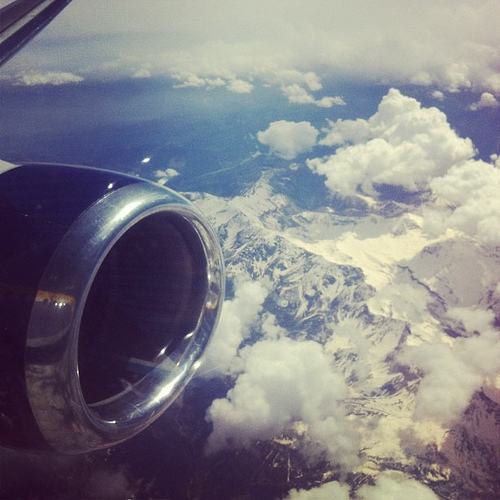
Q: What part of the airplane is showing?
A: Engine.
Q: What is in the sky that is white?
A: Clouds.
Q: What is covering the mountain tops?
A: Snow.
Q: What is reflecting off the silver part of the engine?
A: Light.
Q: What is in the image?
A: Cloud.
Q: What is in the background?
A: Wooded forest area.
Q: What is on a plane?
A: Engine.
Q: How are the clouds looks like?
A: White.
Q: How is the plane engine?
A: Blue and silver.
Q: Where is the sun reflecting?
A: Around the silver circle.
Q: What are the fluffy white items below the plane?
A: Clouds.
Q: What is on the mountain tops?
A: Snow.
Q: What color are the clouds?
A: White.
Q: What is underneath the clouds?
A: The mountains.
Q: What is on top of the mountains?
A: Snow.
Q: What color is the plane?
A: Black.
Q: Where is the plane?
A: In the sky.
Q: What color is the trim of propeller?
A: Silver.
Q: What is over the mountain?
A: The clouds.